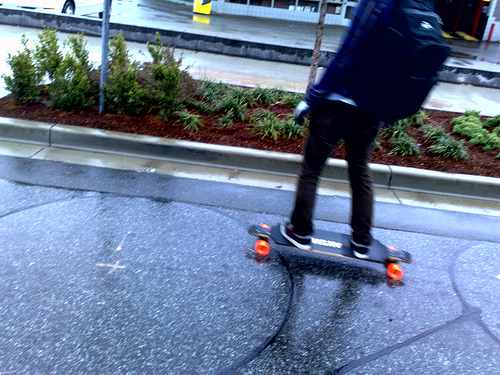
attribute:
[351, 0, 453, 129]
backpack — navy colored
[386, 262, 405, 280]
wheel — large, orange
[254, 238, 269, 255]
wheel — large, orange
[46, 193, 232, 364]
road — grey, dark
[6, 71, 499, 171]
dirt — brown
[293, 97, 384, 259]
jeans — black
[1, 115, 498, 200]
curb — concrete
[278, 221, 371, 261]
shoes — black, white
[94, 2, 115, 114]
pole — grey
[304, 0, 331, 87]
pole — grey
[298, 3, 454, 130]
backpack — black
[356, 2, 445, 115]
backpack — black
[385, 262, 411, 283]
wheel — bright, orange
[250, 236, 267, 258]
wheel — orange, bright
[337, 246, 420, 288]
shoes — black, white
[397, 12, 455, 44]
logo — white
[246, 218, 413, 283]
skateboard — black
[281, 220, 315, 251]
skate shoes — black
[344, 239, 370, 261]
skate shoes — black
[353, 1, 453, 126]
bag — book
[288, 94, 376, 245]
pants — black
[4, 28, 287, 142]
plants — green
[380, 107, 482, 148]
plants — green